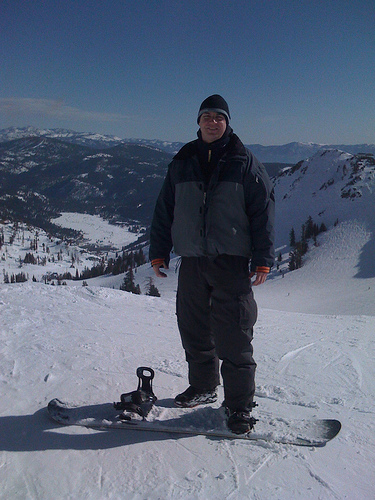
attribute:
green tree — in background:
[121, 267, 140, 297]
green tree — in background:
[72, 266, 83, 280]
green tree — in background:
[133, 280, 143, 293]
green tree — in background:
[274, 250, 284, 262]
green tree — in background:
[121, 266, 135, 292]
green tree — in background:
[135, 281, 141, 293]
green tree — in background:
[72, 265, 82, 280]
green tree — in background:
[76, 264, 81, 278]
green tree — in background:
[145, 280, 161, 297]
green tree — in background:
[115, 265, 136, 299]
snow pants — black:
[174, 257, 257, 417]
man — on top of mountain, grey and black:
[146, 90, 277, 441]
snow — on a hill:
[29, 299, 113, 372]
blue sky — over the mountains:
[33, 21, 303, 91]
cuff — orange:
[238, 248, 304, 295]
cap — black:
[195, 84, 252, 146]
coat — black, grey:
[164, 119, 294, 269]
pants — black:
[152, 240, 291, 417]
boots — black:
[169, 358, 282, 443]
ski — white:
[49, 354, 360, 476]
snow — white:
[271, 323, 367, 410]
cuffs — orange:
[236, 260, 293, 284]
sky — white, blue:
[14, 46, 176, 146]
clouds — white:
[7, 79, 139, 138]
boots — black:
[178, 318, 316, 464]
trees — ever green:
[49, 224, 130, 297]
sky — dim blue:
[178, 12, 318, 117]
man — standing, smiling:
[155, 86, 247, 439]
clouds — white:
[50, 74, 137, 125]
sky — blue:
[33, 17, 300, 79]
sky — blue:
[70, 14, 268, 90]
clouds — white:
[9, 77, 157, 144]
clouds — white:
[30, 79, 129, 161]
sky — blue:
[113, 25, 258, 99]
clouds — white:
[27, 68, 150, 143]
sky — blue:
[129, 23, 289, 100]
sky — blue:
[51, 87, 179, 132]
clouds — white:
[3, 43, 162, 158]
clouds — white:
[16, 81, 144, 129]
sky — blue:
[97, 17, 288, 100]